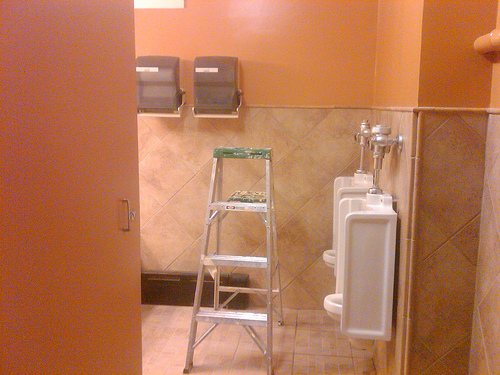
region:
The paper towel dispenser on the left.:
[133, 58, 186, 120]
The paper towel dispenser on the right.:
[190, 58, 241, 120]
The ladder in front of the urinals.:
[188, 130, 284, 373]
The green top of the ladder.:
[210, 138, 275, 163]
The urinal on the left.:
[328, 123, 374, 290]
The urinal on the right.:
[335, 167, 394, 349]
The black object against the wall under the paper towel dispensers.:
[143, 263, 246, 305]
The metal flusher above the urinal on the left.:
[350, 113, 372, 179]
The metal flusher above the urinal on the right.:
[370, 123, 402, 201]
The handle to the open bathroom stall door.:
[124, 188, 131, 231]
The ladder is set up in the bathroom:
[181, 134, 313, 373]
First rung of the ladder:
[193, 263, 283, 341]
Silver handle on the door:
[92, 169, 154, 244]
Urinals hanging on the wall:
[310, 172, 387, 372]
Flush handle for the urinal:
[330, 118, 440, 171]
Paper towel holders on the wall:
[136, 43, 256, 128]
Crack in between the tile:
[287, 324, 306, 373]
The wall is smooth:
[236, 25, 338, 100]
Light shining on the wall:
[212, 5, 379, 62]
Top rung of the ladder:
[211, 140, 289, 172]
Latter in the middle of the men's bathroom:
[1, 0, 499, 374]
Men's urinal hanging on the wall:
[314, 113, 409, 352]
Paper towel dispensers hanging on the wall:
[132, 50, 256, 126]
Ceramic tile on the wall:
[146, 118, 373, 301]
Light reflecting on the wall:
[223, 1, 299, 39]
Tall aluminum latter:
[176, 135, 288, 373]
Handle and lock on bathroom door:
[99, 184, 149, 254]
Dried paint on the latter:
[228, 188, 270, 204]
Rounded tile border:
[411, 103, 494, 121]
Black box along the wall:
[141, 263, 256, 316]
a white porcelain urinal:
[325, 190, 399, 346]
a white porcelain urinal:
[324, 168, 373, 274]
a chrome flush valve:
[368, 131, 403, 193]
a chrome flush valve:
[350, 119, 373, 172]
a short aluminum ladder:
[180, 143, 288, 368]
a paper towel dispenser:
[187, 52, 245, 121]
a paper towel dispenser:
[135, 50, 180, 117]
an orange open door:
[0, 0, 138, 373]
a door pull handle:
[118, 193, 132, 233]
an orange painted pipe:
[470, 28, 498, 56]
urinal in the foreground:
[322, 196, 397, 342]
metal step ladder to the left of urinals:
[183, 147, 283, 374]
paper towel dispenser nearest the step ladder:
[192, 56, 244, 118]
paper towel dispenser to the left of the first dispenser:
[134, 54, 185, 119]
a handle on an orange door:
[121, 197, 132, 234]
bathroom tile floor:
[143, 307, 373, 374]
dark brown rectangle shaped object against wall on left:
[143, 271, 248, 306]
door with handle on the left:
[3, 0, 135, 372]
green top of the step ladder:
[214, 146, 271, 158]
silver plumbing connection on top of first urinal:
[366, 124, 403, 194]